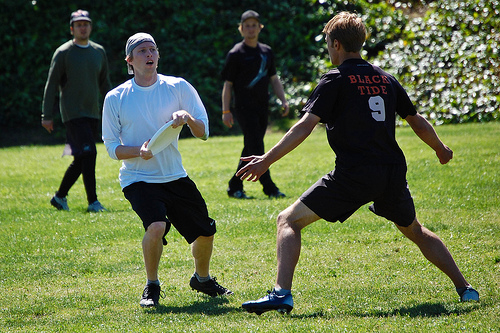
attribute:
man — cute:
[220, 7, 481, 312]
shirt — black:
[304, 50, 418, 158]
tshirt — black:
[227, 49, 277, 107]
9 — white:
[362, 94, 388, 122]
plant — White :
[0, 2, 497, 117]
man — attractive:
[101, 32, 234, 308]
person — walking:
[221, 8, 291, 199]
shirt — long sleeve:
[46, 39, 110, 141]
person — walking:
[237, 11, 482, 311]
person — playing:
[236, 42, 498, 307]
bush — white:
[279, 2, 499, 125]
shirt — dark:
[298, 61, 420, 181]